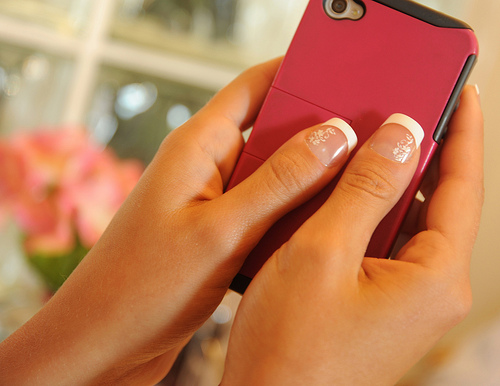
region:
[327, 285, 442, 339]
the hand is light skinned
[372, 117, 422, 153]
this is the nail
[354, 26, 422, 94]
the cell phone is red in color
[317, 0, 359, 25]
this is the camera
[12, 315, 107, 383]
this is the hand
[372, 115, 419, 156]
the nail is beutiful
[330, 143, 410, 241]
this is the thumb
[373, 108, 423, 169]
french tip nail with floral design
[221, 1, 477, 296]
pink and black cell phone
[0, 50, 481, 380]
a woman's manicured hands holding a cellphone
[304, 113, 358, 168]
left french tipped nail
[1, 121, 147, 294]
blurry pink flowers in the background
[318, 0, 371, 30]
camera lens on the cellphone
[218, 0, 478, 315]
the cellphone has a pink cover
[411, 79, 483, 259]
the woman's right index finger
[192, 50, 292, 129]
the woman's left index finger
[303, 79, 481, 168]
the woman has manicured nails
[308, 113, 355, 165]
this is a nail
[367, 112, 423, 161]
this is a nail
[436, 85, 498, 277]
this is a finger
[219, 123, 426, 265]
these are fingers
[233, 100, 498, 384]
this is a hand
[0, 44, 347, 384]
this is a hand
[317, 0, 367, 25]
this is a phone camera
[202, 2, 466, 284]
this is a phone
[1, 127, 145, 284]
these are flowers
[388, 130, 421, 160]
this is a drawing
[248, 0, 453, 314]
phone case is pink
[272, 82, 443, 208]
French tip on the nails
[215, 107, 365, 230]
thumb of a person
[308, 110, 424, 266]
thumb of a person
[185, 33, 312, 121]
finger of a person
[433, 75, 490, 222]
finger of a person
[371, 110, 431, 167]
nail of a person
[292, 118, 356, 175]
nail of a person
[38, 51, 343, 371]
hand of a person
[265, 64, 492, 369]
hand of a person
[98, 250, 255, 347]
palm of a person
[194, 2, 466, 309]
person holding a phone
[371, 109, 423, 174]
white design drawn on a french tip nail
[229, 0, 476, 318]
a phone in a pink and black case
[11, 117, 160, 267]
a pink flower in the distance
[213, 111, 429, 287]
Fingers of a woman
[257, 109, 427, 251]
Fingers of a woman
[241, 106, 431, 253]
Fingers of a woman